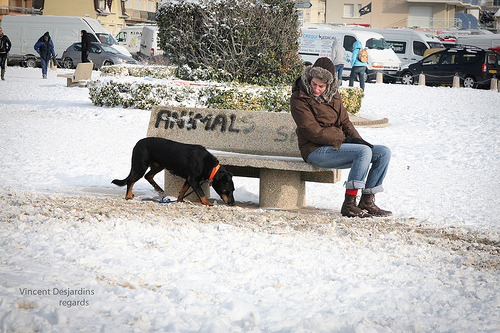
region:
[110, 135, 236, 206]
a black dog standing beside a cement bench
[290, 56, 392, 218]
a man in a brown winter jacket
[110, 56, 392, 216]
a dog and man outdoors in a public park area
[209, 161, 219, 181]
a red collar on the black dog's neck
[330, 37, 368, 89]
two people walking on the right side of the park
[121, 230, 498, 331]
white snow covering the ground at the park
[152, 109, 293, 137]
graffiti on the back of a stone bench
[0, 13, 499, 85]
vehicles parked beside the park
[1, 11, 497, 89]
automobiles in a parking lot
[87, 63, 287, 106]
bushes covered with snow in the landscaping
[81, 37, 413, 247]
Person sitting on concrete bench.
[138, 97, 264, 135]
The word ANIMAL in bold black letters.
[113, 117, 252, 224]
A dog sniffing the ground.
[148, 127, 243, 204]
Red collar on the dog.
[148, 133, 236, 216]
A leash attached to the dog's collar.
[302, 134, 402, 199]
A pair of blue jeans.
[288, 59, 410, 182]
Person wearing winter coat.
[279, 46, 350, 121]
Fur around hood of coat.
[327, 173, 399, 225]
A pair of boots.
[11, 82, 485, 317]
Snow on the ground.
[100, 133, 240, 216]
black dog sniffing the snow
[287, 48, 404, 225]
person sitting on a bench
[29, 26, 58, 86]
person walking in the snow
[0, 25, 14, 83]
person walking in the snow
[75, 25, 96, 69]
person walking in the snow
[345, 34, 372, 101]
person walking in the snow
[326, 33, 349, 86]
person walking in the snow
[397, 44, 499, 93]
car parked in a lot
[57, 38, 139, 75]
car parked in a lot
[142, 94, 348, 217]
stone bench in the snow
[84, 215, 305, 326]
The ground is snow covered.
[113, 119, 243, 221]
The dog is black.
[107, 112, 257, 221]
The dog is sniffing.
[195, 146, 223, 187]
His collar is red.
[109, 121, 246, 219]
The dog is walking.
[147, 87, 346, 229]
The bench is concrete.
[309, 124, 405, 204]
She is wearing jeans.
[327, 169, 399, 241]
Her boots are brown.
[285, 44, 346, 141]
Her jacket is brown.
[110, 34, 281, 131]
The bush is snow covered.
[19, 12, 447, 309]
A winter day with snow on the ground.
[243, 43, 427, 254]
A person sitting on a bench.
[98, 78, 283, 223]
A dog sniffing the ground next to a bench.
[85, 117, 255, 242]
A black dog with a red collar.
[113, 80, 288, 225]
A bench with the word "Animals" painted on it.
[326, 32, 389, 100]
Two people walking in the snow.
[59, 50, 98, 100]
An empty bench in a park.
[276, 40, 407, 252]
Person wearing a brown coat and hat.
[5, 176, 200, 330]
A snow-covered lawn.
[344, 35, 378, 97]
A person wearing a blue coat.